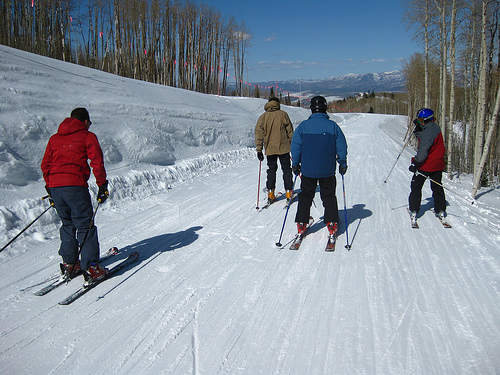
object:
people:
[290, 95, 348, 234]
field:
[0, 153, 500, 375]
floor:
[4, 110, 497, 372]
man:
[41, 107, 108, 282]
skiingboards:
[34, 247, 139, 306]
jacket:
[40, 117, 107, 188]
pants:
[50, 186, 101, 270]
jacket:
[290, 113, 348, 168]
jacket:
[410, 117, 446, 172]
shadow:
[19, 226, 204, 302]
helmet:
[415, 108, 435, 124]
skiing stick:
[275, 175, 298, 250]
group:
[41, 96, 447, 284]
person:
[254, 97, 294, 198]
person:
[407, 108, 446, 221]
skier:
[39, 107, 109, 288]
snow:
[0, 305, 500, 375]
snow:
[345, 120, 375, 133]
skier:
[290, 96, 348, 235]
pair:
[288, 216, 338, 252]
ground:
[0, 44, 500, 375]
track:
[125, 288, 222, 372]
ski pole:
[65, 200, 99, 285]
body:
[41, 130, 107, 270]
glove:
[96, 180, 110, 204]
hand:
[96, 180, 109, 204]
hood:
[57, 117, 86, 134]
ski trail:
[0, 113, 500, 374]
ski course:
[0, 111, 500, 375]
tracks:
[347, 285, 500, 375]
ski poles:
[0, 205, 50, 253]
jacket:
[254, 100, 294, 155]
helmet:
[309, 96, 327, 114]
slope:
[0, 44, 303, 200]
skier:
[408, 108, 446, 214]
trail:
[5, 306, 164, 375]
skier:
[255, 97, 294, 200]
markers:
[0, 0, 246, 98]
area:
[0, 0, 348, 209]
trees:
[254, 84, 261, 98]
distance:
[226, 71, 459, 153]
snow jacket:
[41, 117, 109, 188]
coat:
[254, 100, 293, 155]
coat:
[290, 113, 348, 178]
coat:
[411, 117, 446, 172]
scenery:
[0, 2, 499, 205]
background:
[0, 0, 500, 205]